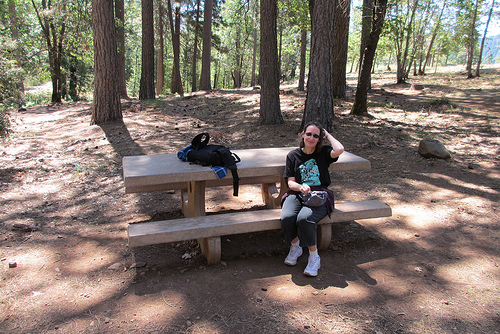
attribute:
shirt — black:
[286, 146, 340, 204]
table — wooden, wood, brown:
[139, 156, 165, 185]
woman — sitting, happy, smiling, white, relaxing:
[286, 129, 336, 281]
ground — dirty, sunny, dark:
[48, 214, 85, 256]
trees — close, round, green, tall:
[44, 5, 115, 52]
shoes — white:
[284, 245, 326, 275]